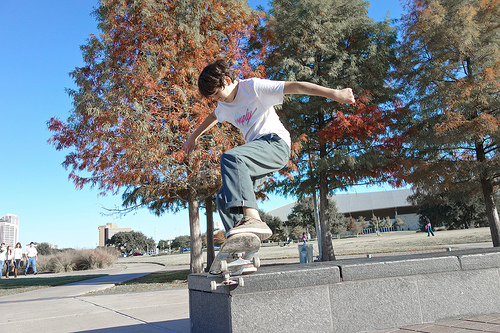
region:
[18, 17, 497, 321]
A park scene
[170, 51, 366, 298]
This boy is skateboarding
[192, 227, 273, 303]
This is a skateboard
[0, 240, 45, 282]
People are watching in the background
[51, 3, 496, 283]
Trees are behind the skateboarder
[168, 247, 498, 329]
The wall is made of stone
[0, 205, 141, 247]
Tall buildings are in the distance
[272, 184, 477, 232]
A house is behind the park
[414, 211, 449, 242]
A person is walking here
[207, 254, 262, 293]
The skateboard's wheels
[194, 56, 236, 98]
boy has brown hair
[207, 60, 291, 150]
boy has white shirt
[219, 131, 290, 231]
boy has blue pants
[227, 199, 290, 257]
boy has grey shoes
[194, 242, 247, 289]
boy is on skateboard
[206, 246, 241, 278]
skateboard has white wheels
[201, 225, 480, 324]
concrete is dark grey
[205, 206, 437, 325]
skateboard is on bench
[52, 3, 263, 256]
tree behind boy is orange and green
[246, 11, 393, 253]
tree behind boy is dark green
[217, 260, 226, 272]
the wheel of a skateboard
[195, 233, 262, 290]
a gray and white skateboard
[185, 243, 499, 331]
a gray concrete wall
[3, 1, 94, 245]
part of a blue sky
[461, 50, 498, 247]
a large tree branch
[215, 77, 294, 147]
a boy's white short sleeve shirt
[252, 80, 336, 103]
the arm of a boy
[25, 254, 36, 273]
a man's blue jean pants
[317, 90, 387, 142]
red tree leaves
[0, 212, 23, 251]
a tall white building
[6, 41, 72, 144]
the sky is clear and visible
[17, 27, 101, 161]
the sky is clear and visible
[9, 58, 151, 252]
the sky is clear and visible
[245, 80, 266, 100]
Boy wearing white shirt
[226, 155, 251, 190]
Boy wearing blue pants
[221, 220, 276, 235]
Boy wearing grey sneakers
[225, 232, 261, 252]
Grey bottom of board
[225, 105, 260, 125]
Pink lettering on shirt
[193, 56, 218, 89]
Boys hair is black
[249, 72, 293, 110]
Boys shirt is short sleeved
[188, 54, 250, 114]
Boy is looking down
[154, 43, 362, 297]
Boy balancing on skateboard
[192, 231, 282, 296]
skateboard under boys feet